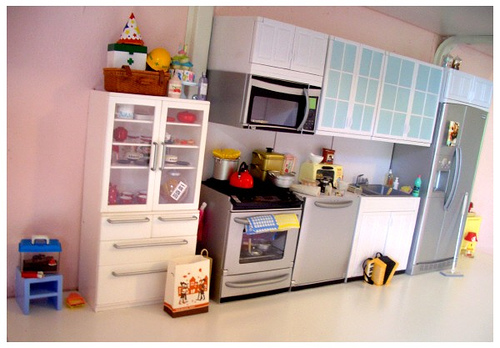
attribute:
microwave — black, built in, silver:
[205, 65, 326, 141]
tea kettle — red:
[223, 159, 262, 194]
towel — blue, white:
[242, 211, 279, 241]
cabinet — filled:
[77, 84, 216, 319]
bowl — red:
[174, 109, 200, 126]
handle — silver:
[103, 215, 152, 229]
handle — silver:
[157, 213, 200, 232]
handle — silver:
[110, 236, 197, 253]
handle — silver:
[108, 264, 171, 280]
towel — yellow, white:
[271, 210, 304, 235]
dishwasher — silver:
[286, 181, 364, 297]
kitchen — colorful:
[6, 5, 498, 346]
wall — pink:
[8, 6, 497, 301]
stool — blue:
[9, 261, 69, 318]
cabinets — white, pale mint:
[203, 12, 495, 154]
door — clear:
[314, 35, 389, 143]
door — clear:
[371, 47, 450, 154]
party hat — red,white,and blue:
[113, 8, 148, 48]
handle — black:
[234, 159, 251, 171]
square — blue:
[325, 35, 348, 75]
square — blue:
[321, 67, 345, 100]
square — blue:
[320, 98, 342, 131]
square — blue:
[380, 51, 407, 86]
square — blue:
[413, 60, 435, 97]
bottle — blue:
[411, 167, 425, 201]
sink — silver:
[350, 168, 426, 205]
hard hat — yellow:
[147, 43, 176, 76]